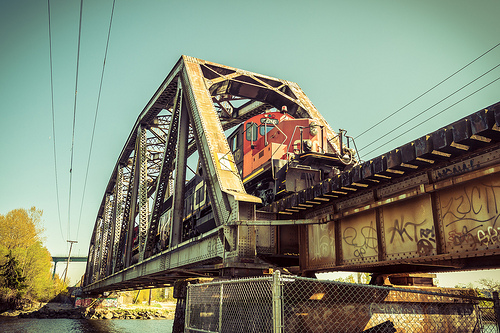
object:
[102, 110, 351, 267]
train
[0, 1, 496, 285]
sky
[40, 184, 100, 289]
cloud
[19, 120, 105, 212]
cloud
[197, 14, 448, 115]
sky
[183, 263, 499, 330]
fence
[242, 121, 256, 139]
windshield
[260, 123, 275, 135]
windshield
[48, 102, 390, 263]
train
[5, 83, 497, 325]
bridge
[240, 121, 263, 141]
window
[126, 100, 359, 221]
train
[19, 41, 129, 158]
cloud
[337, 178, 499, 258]
graffiti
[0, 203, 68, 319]
tree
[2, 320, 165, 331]
water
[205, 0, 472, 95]
sky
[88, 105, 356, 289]
train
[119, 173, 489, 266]
bridge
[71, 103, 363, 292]
train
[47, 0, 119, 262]
electrical lines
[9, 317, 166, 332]
water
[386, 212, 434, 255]
graffiti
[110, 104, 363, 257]
train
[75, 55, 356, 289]
bridge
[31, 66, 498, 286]
bridge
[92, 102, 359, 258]
train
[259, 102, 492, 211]
track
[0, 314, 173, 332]
water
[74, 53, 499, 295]
bridge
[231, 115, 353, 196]
traincar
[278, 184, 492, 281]
bridge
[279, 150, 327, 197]
floor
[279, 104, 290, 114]
light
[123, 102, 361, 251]
train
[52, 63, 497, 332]
bridge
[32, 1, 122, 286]
power lines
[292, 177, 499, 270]
metal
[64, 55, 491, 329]
train bridge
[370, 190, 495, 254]
graffiti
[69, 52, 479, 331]
bridge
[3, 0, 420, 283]
sky